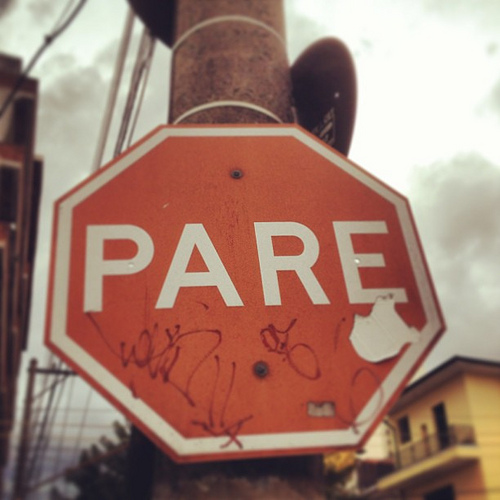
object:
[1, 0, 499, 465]
residential area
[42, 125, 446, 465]
sign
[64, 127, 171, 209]
borders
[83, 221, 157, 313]
letters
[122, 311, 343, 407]
graffiti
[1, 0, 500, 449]
sky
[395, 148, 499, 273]
clouds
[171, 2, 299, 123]
pole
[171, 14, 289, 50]
circles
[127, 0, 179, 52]
signs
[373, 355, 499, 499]
building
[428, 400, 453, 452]
door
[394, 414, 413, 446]
windows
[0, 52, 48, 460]
building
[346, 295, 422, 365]
spot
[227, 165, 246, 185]
screw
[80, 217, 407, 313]
pare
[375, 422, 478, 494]
balcony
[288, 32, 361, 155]
sign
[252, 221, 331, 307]
r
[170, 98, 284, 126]
straps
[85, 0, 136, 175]
lines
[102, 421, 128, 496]
trees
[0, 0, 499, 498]
background